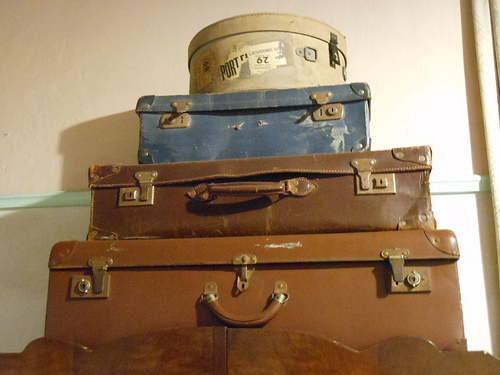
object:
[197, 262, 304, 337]
handle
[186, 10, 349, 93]
box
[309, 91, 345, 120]
latch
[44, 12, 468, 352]
stack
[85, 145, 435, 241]
suitcase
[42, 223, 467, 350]
box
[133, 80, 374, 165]
box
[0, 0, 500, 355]
wall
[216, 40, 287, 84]
sticker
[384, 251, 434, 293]
lock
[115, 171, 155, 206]
lock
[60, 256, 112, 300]
lock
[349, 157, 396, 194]
latch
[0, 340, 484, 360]
floor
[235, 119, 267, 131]
holes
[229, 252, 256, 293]
latch